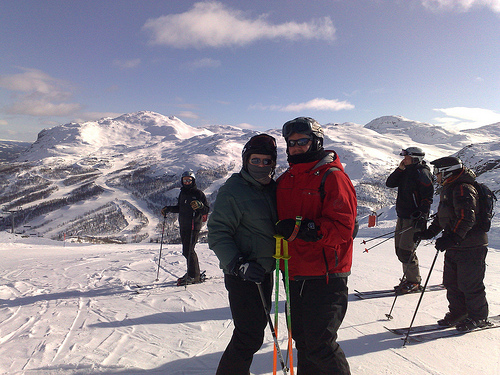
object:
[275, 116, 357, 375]
man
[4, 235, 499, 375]
ski slope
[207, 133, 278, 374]
woman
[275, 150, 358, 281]
ski coat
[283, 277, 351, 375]
ski pants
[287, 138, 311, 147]
sunglasses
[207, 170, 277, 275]
ski coat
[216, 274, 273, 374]
ski pants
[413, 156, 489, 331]
man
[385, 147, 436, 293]
person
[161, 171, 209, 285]
person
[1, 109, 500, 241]
mountains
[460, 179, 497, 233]
backpack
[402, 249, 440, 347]
ski pole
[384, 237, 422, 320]
ski pole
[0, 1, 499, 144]
sky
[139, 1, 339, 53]
cloud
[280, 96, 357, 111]
cloud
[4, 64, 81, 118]
cloud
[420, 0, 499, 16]
cloud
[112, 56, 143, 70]
cloud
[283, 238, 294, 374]
ski pole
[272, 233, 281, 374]
ski pole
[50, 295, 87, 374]
ski tracks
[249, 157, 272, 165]
sunglasses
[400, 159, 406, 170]
hand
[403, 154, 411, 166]
face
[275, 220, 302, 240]
hand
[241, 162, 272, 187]
scarf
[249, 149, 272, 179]
face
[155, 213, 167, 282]
ski pole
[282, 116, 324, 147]
helmet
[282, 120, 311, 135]
goggles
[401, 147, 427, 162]
helmet